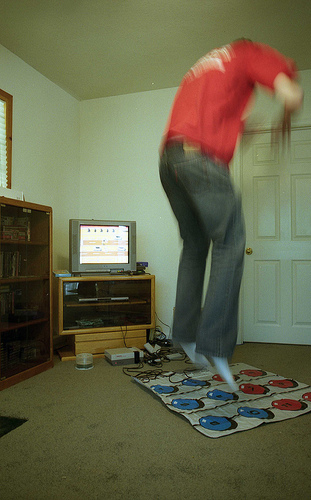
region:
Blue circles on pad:
[129, 374, 275, 433]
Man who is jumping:
[148, 19, 305, 389]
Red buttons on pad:
[209, 366, 308, 421]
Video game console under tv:
[100, 334, 149, 369]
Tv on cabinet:
[62, 206, 149, 287]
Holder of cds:
[67, 348, 100, 378]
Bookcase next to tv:
[2, 197, 60, 380]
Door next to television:
[231, 121, 309, 351]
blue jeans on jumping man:
[134, 138, 260, 360]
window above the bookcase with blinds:
[0, 88, 16, 189]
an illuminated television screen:
[76, 221, 131, 264]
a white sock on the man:
[209, 349, 240, 391]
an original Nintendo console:
[101, 344, 144, 367]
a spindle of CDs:
[72, 348, 95, 370]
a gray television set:
[66, 215, 138, 275]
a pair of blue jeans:
[152, 142, 248, 360]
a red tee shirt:
[157, 39, 303, 171]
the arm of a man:
[247, 42, 310, 154]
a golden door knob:
[244, 245, 253, 256]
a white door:
[233, 117, 310, 346]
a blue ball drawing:
[196, 408, 231, 434]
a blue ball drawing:
[173, 397, 199, 410]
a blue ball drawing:
[151, 379, 175, 394]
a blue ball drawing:
[236, 402, 268, 422]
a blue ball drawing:
[207, 388, 236, 402]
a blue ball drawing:
[184, 375, 207, 386]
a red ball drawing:
[271, 396, 302, 410]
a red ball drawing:
[238, 378, 261, 393]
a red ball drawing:
[269, 376, 294, 386]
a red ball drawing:
[240, 364, 262, 375]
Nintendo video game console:
[97, 345, 152, 373]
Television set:
[63, 214, 147, 270]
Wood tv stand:
[54, 269, 162, 362]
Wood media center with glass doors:
[0, 185, 57, 395]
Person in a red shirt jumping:
[144, 29, 304, 419]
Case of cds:
[70, 348, 93, 372]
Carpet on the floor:
[52, 408, 137, 461]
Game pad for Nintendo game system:
[133, 363, 304, 430]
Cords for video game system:
[115, 362, 154, 369]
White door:
[236, 121, 304, 328]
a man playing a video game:
[157, 34, 303, 398]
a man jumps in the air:
[165, 25, 293, 382]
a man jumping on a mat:
[156, 34, 310, 430]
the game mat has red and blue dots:
[141, 349, 301, 436]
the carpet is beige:
[35, 341, 307, 499]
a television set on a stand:
[70, 216, 155, 277]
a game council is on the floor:
[97, 338, 178, 369]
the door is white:
[236, 165, 310, 344]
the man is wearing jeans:
[165, 23, 270, 391]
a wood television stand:
[59, 276, 160, 358]